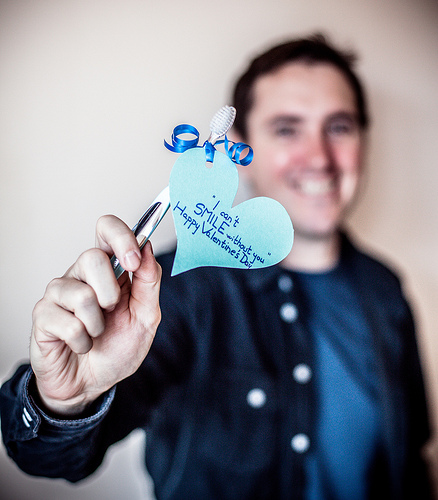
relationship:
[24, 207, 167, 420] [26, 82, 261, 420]
hand holding toothbrush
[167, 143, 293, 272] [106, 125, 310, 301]
note tied on toothbrush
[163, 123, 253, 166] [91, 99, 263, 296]
ribbon tied around toothbrush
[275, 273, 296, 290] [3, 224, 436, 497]
button on shirt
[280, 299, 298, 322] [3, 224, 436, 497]
button on shirt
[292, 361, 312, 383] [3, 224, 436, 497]
button on shirt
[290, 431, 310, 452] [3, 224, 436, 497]
button on shirt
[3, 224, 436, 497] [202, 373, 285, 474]
shirt has pocket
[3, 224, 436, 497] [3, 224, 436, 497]
shirt under shirt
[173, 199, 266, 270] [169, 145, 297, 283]
note on paper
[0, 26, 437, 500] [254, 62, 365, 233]
man has face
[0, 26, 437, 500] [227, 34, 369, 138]
man has hair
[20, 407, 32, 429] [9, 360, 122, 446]
buttons on cuff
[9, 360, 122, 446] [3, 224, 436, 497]
cuff on shirt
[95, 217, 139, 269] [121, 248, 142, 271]
finger has fingernail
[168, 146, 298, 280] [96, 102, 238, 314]
tag on toothbrush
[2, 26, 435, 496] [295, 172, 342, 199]
man has mouth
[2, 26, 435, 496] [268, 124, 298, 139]
man has eye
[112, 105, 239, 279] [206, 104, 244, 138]
toothbrush has head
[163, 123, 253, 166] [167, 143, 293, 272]
ribbon holding note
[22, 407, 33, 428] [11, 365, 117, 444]
buttons on cuff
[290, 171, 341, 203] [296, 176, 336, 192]
smile shows teeth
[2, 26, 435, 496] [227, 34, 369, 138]
man has hair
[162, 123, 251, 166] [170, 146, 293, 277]
ribbon wrapped around heart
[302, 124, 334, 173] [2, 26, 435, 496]
nose of man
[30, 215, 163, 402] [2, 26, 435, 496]
hand of man